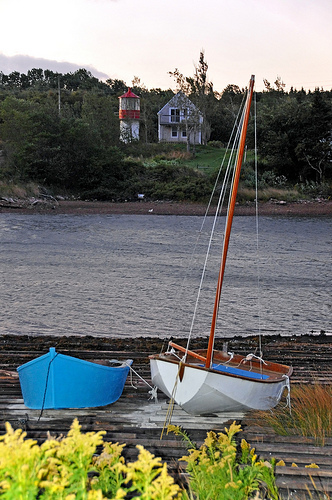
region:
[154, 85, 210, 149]
two story gray house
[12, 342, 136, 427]
small blue boat on dock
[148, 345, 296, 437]
white sail boat on dock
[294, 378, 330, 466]
weeds growing on weathered boards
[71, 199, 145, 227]
water and shoreline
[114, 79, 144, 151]
round red light house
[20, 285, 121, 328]
water with small ripples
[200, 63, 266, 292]
red sail boat mast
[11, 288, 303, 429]
two boats on dry dock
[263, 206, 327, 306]
body of water and shore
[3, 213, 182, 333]
Smooth blue water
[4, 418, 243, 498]
Green and yellow grass and shrubbery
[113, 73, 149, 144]
Red and white lighthouse near the forest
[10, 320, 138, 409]
Blue painted boat near the water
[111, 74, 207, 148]
House with slanted roof next to the lighthouse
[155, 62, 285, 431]
White boat with an orange mast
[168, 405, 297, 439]
Wooden dock covered in grass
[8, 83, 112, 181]
Thick stand of green trees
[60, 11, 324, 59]
Pale white sky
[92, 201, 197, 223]
Rocky shoreline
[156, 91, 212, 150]
a house is on a hill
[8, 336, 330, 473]
boats are anchored on the river bank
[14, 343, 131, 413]
the boat is blue on the bank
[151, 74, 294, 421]
the sailboat has a wooden mast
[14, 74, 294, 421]
the boats are next to each other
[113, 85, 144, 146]
a lighthouse has a red top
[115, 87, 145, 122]
windows surround the lighthouse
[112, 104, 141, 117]
a fence surrounds the outside of the light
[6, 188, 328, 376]
the water is at low tide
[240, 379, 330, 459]
reeds are growing through the planks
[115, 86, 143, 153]
red and white house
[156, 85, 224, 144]
brown and white house in the back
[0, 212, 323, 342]
blue calm lake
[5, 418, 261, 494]
light freen bushes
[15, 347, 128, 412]
blue raft in the dock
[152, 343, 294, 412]
white and oranges rafts in the dock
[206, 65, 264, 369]
large orange pole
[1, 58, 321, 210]
green bushes in the back of the house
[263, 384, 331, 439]
green and orange grass at the right of rafts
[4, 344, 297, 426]
two rafts in a dock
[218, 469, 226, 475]
part of a flower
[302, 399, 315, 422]
part of a grass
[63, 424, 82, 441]
tip of a plant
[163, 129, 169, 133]
part of a building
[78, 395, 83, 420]
bottom of a boat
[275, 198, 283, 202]
part of a shore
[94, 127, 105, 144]
part of a forest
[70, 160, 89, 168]
edge of a shore